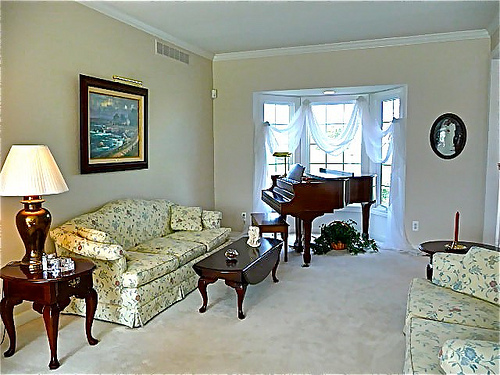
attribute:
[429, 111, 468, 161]
picture — oval, oval shaped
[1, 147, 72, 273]
lamp — gold, on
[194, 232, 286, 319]
table — wood, brown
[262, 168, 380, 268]
piano — brown wood, brown, wood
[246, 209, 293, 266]
bench — brown, brown wood, wood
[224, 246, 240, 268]
candle — red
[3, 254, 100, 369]
end table — wood, brown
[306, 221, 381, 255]
plant — green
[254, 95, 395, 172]
curtains — white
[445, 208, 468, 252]
candle — red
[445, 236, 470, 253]
candle holder — gold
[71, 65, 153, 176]
frame — brown